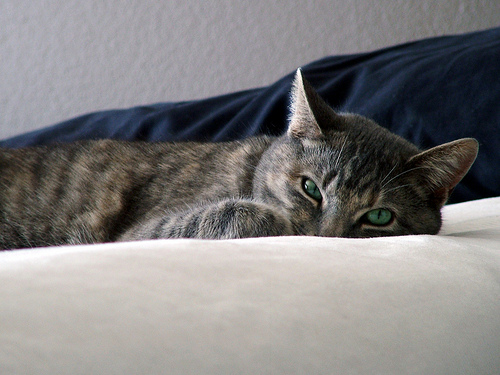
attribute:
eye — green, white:
[295, 170, 328, 206]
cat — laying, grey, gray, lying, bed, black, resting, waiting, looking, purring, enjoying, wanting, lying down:
[0, 27, 482, 279]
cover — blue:
[358, 28, 473, 131]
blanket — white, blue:
[103, 227, 424, 372]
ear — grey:
[279, 70, 323, 133]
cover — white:
[238, 259, 413, 352]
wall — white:
[172, 6, 242, 79]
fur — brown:
[181, 153, 219, 191]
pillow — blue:
[357, 67, 431, 91]